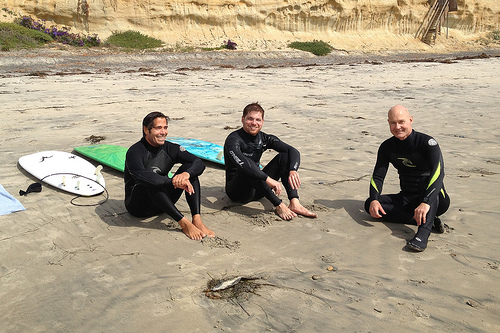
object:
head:
[388, 102, 413, 137]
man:
[365, 105, 449, 251]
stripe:
[424, 159, 442, 190]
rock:
[317, 255, 347, 291]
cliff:
[103, 8, 270, 66]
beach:
[268, 75, 345, 92]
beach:
[359, 302, 498, 331]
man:
[122, 111, 216, 241]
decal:
[424, 135, 439, 148]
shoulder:
[415, 128, 445, 152]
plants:
[108, 27, 158, 49]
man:
[222, 101, 318, 221]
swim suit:
[122, 138, 209, 224]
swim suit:
[221, 128, 301, 209]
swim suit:
[362, 128, 450, 239]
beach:
[45, 81, 114, 124]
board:
[17, 151, 107, 196]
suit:
[123, 140, 205, 220]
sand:
[59, 237, 126, 283]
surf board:
[73, 138, 126, 172]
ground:
[386, 299, 489, 333]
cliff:
[297, 2, 351, 53]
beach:
[140, 84, 223, 107]